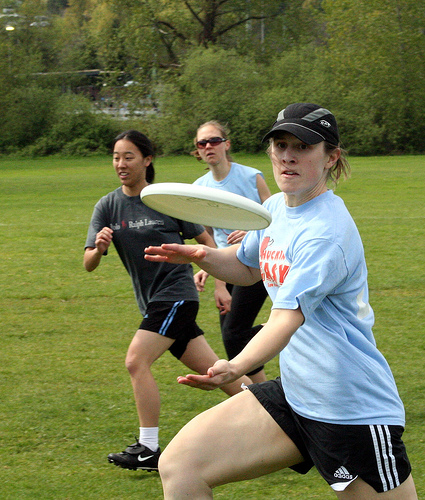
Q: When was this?
A: Daytime.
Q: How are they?
A: In motion.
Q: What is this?
A: A plate.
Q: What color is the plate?
A: White.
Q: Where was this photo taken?
A: In a park.